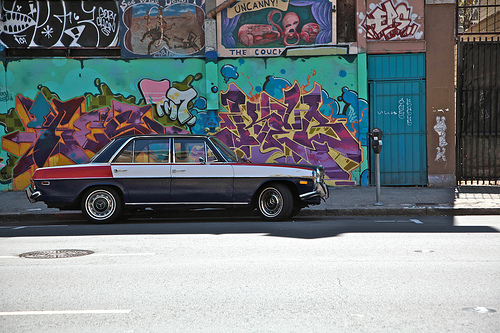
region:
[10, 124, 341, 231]
black, white and red car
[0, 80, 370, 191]
colorful graffiti on a wall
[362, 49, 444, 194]
blue barred door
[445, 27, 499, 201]
black metal gate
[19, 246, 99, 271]
metal sewer cover in road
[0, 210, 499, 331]
grey paved street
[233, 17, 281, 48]
painted red couch on wall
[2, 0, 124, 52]
black and white graffiti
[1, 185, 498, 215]
side walk mostly in shadow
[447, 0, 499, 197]
black metal gated entrance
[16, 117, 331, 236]
a car parked on the street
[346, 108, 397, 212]
a black parking meter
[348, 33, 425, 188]
a tall light blue door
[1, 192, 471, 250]
a shadow of a building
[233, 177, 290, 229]
the car wheel is black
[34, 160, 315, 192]
the side of the car is white and red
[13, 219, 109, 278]
a man whole in the street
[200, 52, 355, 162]
graffiti on the wall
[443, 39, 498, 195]
a black gated door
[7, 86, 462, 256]
shady side of the street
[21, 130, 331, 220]
Small car is parked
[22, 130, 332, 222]
Small car near parking meter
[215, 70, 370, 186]
Large graffiti on wall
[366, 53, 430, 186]
Blue metal door behind parking meter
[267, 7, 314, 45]
Octopus graffiti on wall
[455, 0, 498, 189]
Black metal gate next to metal blue door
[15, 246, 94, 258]
Manhole cover on street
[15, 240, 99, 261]
Manhole cover near car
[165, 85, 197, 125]
number 7 graffiti on wall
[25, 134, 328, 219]
Parked car next to sidewalk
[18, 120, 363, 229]
car parked on the street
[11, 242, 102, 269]
manhole cover on the street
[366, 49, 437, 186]
gate over a teal door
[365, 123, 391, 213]
parking meter on the curb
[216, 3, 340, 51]
octopus painted on the wall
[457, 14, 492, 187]
security gate over a storefront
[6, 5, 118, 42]
black and white graffiti on the wall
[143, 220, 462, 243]
shadow of the building on the street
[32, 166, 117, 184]
red stripe on the car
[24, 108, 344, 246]
A car is visible.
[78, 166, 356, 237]
A car is visible.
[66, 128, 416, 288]
A car is visible.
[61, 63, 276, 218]
A car is visible.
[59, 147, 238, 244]
A car is visible.